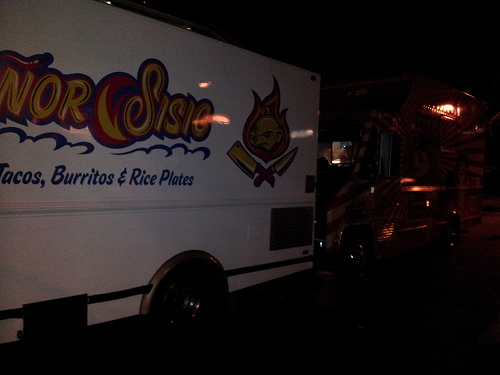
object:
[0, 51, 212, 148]
logo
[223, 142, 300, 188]
image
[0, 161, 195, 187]
blue letter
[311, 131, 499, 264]
image truck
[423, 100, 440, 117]
light reflection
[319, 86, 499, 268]
food truck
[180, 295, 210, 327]
rim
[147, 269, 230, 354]
wheel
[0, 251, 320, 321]
stripe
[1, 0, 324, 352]
bus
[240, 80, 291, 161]
fire symbol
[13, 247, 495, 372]
street